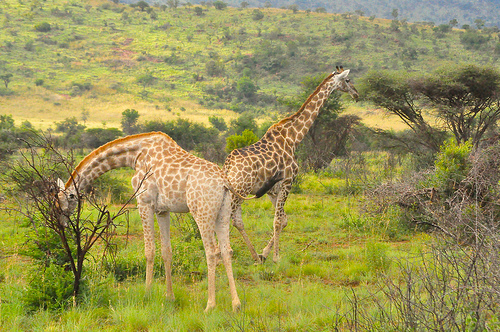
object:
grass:
[244, 282, 318, 332]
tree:
[120, 108, 141, 135]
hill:
[2, 2, 246, 112]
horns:
[336, 65, 345, 72]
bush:
[0, 123, 154, 309]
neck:
[268, 77, 338, 146]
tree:
[164, 53, 179, 69]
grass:
[117, 305, 181, 332]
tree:
[337, 226, 500, 332]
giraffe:
[53, 130, 284, 314]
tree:
[135, 72, 153, 90]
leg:
[186, 187, 226, 301]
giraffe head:
[336, 65, 360, 103]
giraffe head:
[51, 177, 80, 231]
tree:
[430, 60, 500, 153]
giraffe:
[221, 65, 359, 264]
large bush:
[355, 60, 500, 153]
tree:
[204, 54, 225, 77]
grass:
[296, 219, 356, 259]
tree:
[0, 73, 15, 89]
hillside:
[1, 72, 275, 140]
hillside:
[229, 7, 499, 114]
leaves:
[22, 222, 68, 264]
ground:
[242, 228, 500, 332]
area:
[0, 174, 500, 332]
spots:
[238, 148, 289, 178]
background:
[0, 0, 500, 134]